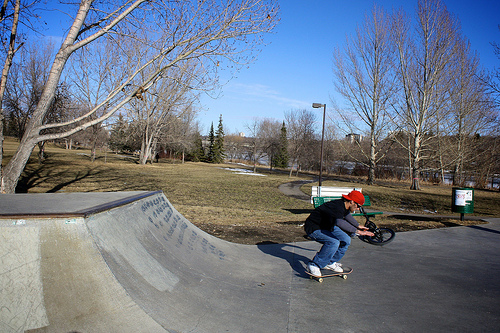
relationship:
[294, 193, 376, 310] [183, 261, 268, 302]
man skating on concrete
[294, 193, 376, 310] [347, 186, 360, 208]
man in red hat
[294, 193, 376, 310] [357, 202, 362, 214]
man in dark sunglasses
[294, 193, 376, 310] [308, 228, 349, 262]
man in blue jeans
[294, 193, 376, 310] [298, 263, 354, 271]
man in white shoes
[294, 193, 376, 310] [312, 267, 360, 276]
man on skateboard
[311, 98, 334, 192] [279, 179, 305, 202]
light by path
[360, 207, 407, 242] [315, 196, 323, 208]
bike by bench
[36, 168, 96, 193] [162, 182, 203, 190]
shadow on grass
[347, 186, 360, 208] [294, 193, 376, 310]
red hat on man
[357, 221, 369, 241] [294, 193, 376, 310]
hand of man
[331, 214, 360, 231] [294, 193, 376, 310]
arm of man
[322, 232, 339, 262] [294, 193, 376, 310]
leg of man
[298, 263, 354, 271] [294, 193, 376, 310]
white shoes of man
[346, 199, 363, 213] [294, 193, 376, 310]
head of man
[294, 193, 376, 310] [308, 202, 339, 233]
man in black tee shirt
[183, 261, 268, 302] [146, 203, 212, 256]
concrete has black characters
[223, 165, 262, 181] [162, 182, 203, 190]
snow on grass